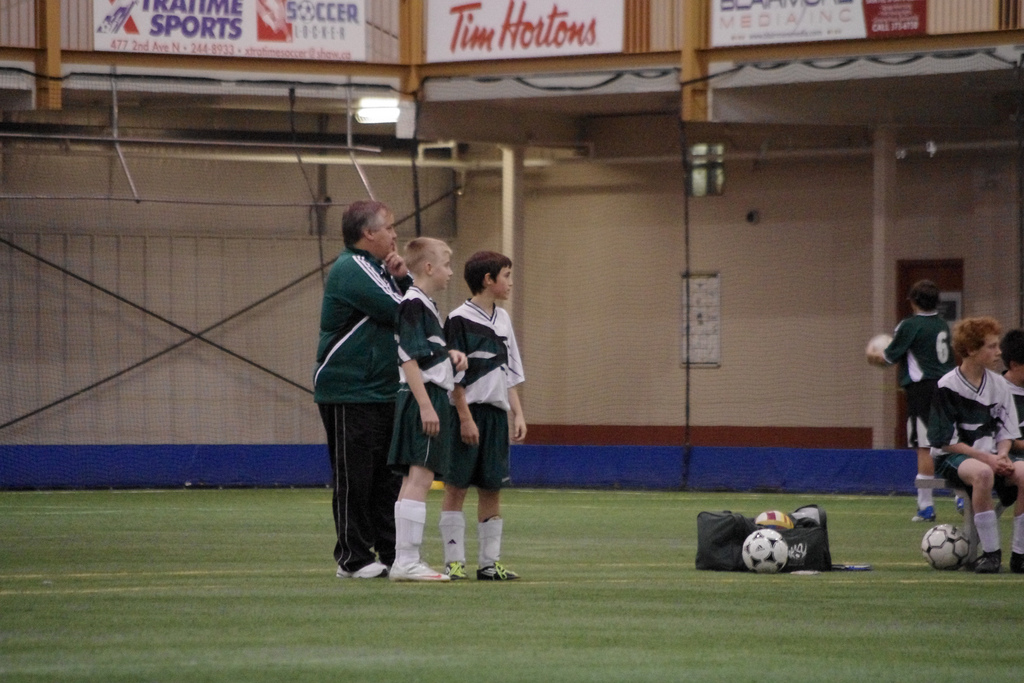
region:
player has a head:
[345, 201, 400, 260]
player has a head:
[403, 237, 454, 295]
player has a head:
[463, 252, 509, 303]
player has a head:
[910, 275, 934, 304]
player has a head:
[952, 311, 1003, 366]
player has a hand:
[462, 414, 478, 441]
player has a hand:
[418, 403, 444, 429]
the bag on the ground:
[691, 487, 846, 585]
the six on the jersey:
[926, 323, 961, 368]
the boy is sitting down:
[914, 305, 1019, 569]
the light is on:
[328, 87, 408, 146]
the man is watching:
[307, 187, 416, 609]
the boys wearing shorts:
[379, 218, 534, 585]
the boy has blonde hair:
[392, 232, 469, 596]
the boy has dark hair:
[435, 247, 530, 587]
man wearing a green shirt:
[304, 196, 407, 585]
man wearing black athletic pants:
[308, 193, 417, 592]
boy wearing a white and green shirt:
[446, 249, 530, 579]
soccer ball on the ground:
[694, 503, 834, 577]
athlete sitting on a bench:
[924, 318, 1022, 565]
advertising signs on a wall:
[81, 3, 929, 62]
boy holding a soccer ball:
[861, 278, 953, 522]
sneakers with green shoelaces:
[437, 557, 530, 583]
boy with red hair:
[920, 315, 1022, 575]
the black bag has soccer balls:
[696, 506, 830, 571]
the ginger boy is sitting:
[921, 311, 1021, 572]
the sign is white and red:
[422, 0, 623, 64]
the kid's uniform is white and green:
[392, 231, 470, 585]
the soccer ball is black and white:
[740, 527, 788, 569]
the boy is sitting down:
[925, 316, 1021, 569]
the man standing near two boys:
[317, 198, 524, 585]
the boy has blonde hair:
[387, 234, 451, 579]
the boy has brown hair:
[441, 253, 528, 583]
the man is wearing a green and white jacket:
[307, 199, 412, 580]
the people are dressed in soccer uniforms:
[311, 192, 1021, 581]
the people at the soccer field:
[0, 0, 1022, 679]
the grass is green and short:
[2, 484, 1020, 680]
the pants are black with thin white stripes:
[313, 395, 399, 574]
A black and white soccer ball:
[725, 512, 796, 585]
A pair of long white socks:
[427, 495, 516, 572]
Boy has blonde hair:
[387, 219, 463, 297]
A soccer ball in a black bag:
[677, 491, 842, 581]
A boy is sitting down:
[909, 298, 1015, 574]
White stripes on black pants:
[299, 380, 407, 573]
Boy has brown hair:
[449, 232, 520, 310]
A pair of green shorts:
[373, 368, 463, 493]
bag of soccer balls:
[689, 500, 835, 578]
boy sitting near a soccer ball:
[919, 315, 1022, 566]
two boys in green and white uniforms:
[399, 227, 532, 589]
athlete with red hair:
[922, 312, 1022, 572]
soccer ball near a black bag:
[691, 502, 837, 582]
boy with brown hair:
[451, 249, 538, 583]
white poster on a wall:
[674, 266, 728, 375]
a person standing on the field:
[316, 198, 400, 454]